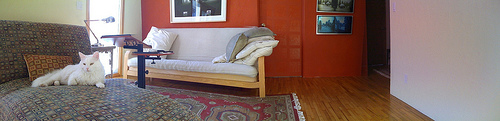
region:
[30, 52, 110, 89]
White cat laying next to a pillow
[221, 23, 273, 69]
stacks of pillows on corner of couch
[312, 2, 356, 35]
two sets of pictures hanging on wall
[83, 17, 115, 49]
a metal lamp is on top of a desk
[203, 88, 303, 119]
multi colored rug has white fringe on end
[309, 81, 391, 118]
floor is made of wood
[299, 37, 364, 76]
this part of the wall is orange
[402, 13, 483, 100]
this part of the wall is white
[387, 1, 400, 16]
the wall has a white light switch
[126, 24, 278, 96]
wooden futon in a room against a orange wall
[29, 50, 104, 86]
white cat laying down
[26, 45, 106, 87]
white cat laying on the bed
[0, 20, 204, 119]
a bed with a cat laying on it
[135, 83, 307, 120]
a red Persian rug on the floor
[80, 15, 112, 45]
a lamp by the window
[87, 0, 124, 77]
a large window on the left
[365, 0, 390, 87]
a doorway on the right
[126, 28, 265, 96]
a futon with a white cushion and many pillows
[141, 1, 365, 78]
an orange wall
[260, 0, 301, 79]
orange closet door being blocked partially by futon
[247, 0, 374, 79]
bright orange wall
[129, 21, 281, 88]
white futon sofa with wood frame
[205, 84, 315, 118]
red persian rug in living room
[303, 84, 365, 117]
shiny brown hardwood floor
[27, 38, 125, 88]
white cat sitting on sofa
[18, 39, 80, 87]
pillow on the sofa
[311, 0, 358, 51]
two pictures on the wall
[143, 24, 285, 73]
many pillos on the futom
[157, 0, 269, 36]
large picture behind the sofa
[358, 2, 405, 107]
entrance to the living room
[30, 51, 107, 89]
beautiful white adult cat resting on a bed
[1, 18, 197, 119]
small bed with a cat resting on it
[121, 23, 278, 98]
white colored futon with light colored wood frame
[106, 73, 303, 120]
large area rug sitting on a hardwood floor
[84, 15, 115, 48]
an adjustable lamp sitting on a small table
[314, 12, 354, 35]
rectangular shaped picture in a frame hanging on an orange wall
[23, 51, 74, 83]
small pillow resting on a bed and sitting near a cat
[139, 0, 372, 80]
large wall section painted orange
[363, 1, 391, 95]
entryway to hallway found to the right of the futon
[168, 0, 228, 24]
large framed picture affixed to a wall hanging above a white futon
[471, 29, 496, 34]
part of a wall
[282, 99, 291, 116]
part of a carpet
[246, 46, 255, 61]
part of a chair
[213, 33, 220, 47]
edge of a chair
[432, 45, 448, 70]
part of a wall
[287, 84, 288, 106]
edge of a carpet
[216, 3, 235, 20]
part of a painting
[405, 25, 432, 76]
edge of a wall